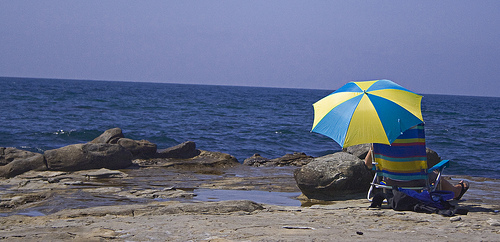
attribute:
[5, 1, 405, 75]
sky — blue, clear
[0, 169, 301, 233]
water — pools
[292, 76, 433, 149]
umbrella — blue, yellow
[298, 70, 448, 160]
umbrella — yellow, blue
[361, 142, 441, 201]
chair — blue, yellow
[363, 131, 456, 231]
chair — yellow, blue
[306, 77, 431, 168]
umbrella — blue, yellow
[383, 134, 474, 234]
person — resting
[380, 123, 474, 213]
person — looking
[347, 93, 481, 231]
someone — resting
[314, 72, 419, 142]
umbrella — blue, yellow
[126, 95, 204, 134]
water — dark blue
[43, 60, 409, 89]
sky — clear  blue